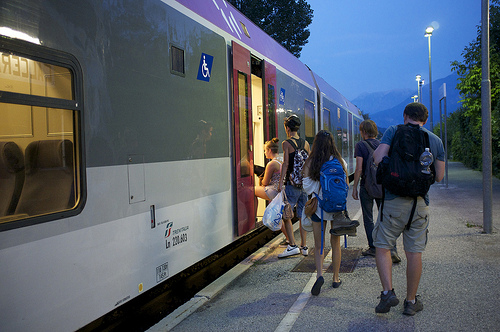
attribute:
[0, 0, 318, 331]
car — green, white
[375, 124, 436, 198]
backpack — black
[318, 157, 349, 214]
backpack — blue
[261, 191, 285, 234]
bag — white, plastic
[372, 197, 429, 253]
pants — khaki, short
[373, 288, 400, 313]
shoe — gray, athletic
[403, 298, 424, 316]
shoe — gray, athletic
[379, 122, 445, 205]
shirt — blue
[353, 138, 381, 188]
shirt — blue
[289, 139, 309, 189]
backpack — black, white, blue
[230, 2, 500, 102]
sky — dark, blue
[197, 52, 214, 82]
sign — blue, white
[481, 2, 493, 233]
pole — metal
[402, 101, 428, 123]
hair — brown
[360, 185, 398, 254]
jeans — blue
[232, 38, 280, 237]
doors — red, open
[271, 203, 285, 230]
writing — blue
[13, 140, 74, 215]
seat — comfortable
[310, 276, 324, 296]
shoe — black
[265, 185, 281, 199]
shorts — gray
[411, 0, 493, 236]
streetlights — lit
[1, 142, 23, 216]
seat — comfortable